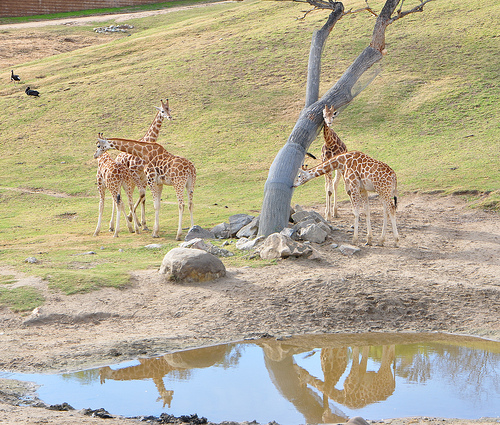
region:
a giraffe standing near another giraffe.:
[89, 129, 206, 236]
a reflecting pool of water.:
[0, 325, 494, 422]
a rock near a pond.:
[153, 229, 240, 288]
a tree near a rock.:
[251, 1, 439, 247]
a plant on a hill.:
[9, 61, 53, 121]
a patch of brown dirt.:
[6, 261, 74, 312]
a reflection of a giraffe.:
[287, 343, 414, 417]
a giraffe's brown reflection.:
[92, 334, 246, 407]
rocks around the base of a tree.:
[201, 179, 331, 280]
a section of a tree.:
[363, 5, 421, 58]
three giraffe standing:
[90, 97, 200, 244]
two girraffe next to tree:
[280, 98, 403, 252]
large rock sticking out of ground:
[155, 241, 232, 291]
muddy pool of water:
[51, 346, 491, 414]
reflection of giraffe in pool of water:
[291, 343, 404, 415]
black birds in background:
[5, 62, 41, 103]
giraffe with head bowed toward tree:
[288, 156, 405, 240]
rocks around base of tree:
[212, 198, 332, 255]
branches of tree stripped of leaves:
[285, 3, 441, 31]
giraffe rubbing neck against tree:
[312, 101, 349, 146]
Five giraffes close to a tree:
[76, 91, 419, 257]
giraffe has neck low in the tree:
[288, 147, 414, 257]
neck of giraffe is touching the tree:
[308, 93, 349, 146]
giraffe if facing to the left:
[287, 147, 413, 251]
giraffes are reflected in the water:
[88, 341, 428, 421]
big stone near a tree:
[148, 238, 234, 290]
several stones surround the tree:
[208, 202, 336, 259]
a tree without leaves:
[249, 0, 456, 109]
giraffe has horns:
[138, 87, 185, 129]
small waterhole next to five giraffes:
[40, 308, 497, 420]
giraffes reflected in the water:
[104, 355, 417, 409]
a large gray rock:
[156, 235, 221, 288]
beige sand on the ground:
[346, 250, 458, 313]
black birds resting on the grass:
[8, 66, 55, 106]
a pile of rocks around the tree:
[229, 210, 328, 251]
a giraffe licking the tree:
[297, 165, 419, 245]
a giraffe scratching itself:
[319, 97, 346, 155]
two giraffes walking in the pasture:
[81, 74, 196, 234]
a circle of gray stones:
[94, 21, 142, 47]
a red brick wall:
[1, 0, 126, 13]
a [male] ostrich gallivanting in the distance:
[1, 65, 21, 90]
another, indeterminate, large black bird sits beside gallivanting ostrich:
[21, 81, 41, 97]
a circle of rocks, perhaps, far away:
[87, 21, 137, 39]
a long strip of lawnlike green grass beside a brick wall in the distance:
[0, 1, 202, 22]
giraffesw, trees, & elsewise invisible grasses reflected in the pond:
[0, 330, 495, 422]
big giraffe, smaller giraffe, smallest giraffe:
[87, 93, 213, 246]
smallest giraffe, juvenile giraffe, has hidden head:
[91, 127, 146, 240]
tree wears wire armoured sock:
[260, 26, 395, 186]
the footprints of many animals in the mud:
[226, 260, 497, 335]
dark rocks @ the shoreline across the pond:
[23, 393, 217, 424]